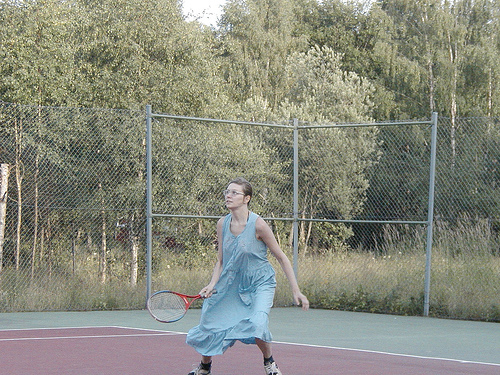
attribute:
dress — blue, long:
[181, 213, 280, 355]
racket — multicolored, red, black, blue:
[146, 287, 217, 325]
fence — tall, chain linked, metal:
[6, 115, 498, 311]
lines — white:
[1, 326, 184, 342]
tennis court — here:
[3, 102, 498, 369]